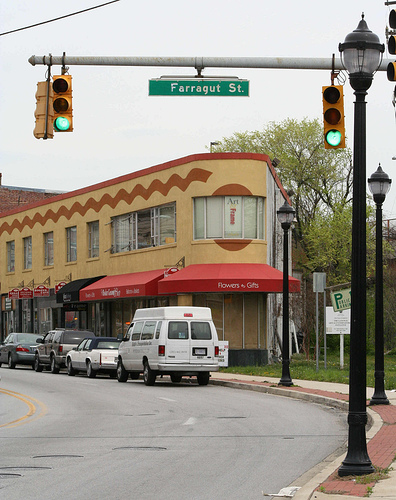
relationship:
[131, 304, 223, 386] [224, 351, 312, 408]
van parked at curb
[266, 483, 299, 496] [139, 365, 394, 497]
paper by curb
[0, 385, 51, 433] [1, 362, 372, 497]
yellow lines on road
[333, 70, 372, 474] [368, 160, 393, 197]
pole with fixture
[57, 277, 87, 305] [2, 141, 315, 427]
canopy on building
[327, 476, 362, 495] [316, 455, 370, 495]
bricks on sidewalk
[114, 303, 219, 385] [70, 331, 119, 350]
car with roof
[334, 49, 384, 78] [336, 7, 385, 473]
light on light pole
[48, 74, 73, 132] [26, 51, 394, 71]
light on pole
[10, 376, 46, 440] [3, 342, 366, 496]
line in road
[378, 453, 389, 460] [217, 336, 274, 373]
brick on wall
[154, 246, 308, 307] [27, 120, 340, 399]
sign on building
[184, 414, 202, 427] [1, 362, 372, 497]
line on road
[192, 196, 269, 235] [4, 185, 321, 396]
window on building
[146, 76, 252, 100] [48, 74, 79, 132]
sign with light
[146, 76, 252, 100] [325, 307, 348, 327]
sign with lettering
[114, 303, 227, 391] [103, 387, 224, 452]
car on pavement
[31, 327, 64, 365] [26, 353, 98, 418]
car on pavement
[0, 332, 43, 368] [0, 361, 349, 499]
car on pavement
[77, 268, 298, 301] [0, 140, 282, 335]
awnings on building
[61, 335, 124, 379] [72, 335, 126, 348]
car with top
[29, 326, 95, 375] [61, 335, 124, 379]
suv in front of car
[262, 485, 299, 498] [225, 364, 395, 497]
paper on ground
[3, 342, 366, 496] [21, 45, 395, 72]
road from pole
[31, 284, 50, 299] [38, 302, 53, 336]
red sign over door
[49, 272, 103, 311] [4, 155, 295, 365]
awning on building